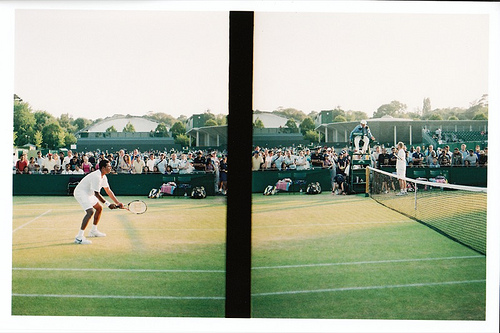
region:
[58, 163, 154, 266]
man holding a tennis racket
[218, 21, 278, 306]
a pole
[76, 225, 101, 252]
man wearing white shoes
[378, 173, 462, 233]
a tennis net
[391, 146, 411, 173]
a person wearing white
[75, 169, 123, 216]
the tennis player wearing white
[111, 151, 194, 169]
people in the audience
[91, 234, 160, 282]
man standing on the tennis court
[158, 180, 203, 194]
bags on the ground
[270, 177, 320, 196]
bags on the ground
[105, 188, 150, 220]
man holding a tennis racket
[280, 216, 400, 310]
tennis court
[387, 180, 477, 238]
tennis net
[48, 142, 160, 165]
people in the audience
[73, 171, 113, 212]
tennis player wearing white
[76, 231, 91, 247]
tennis player wearing white shoes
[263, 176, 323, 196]
bags on the side of court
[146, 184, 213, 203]
bags on the ground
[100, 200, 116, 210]
white sweat band on arm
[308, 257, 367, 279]
white line on tennis court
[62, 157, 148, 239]
A MAN IS HOLD A TENNIS RACQUET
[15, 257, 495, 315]
WHITE LINES ARE ON THE COURT FLOOR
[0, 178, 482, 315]
COURT FLOOR IS GREEN IN COLOR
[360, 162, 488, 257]
A NET SEPARATES THE SIDES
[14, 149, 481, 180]
SPECTATORS ARE WATCHING THE GAME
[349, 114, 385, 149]
REFEREE IS SITTING IN THE CHAIR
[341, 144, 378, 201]
REFEREE STAND IS GREEN IN COLOR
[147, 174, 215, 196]
BAGS ARE ON THE SIDELINE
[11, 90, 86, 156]
TREES ARE IN THE BACKGROUND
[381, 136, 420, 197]
SOMEONE IS SPEAKING WITH THE REFEREE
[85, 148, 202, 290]
a man in white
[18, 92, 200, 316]
a man in white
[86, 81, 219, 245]
a man in white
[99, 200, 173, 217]
MAN IS HOLDING THE TENNIS RACKET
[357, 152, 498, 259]
A NET SEPARATES THE SIDES OF THE COURT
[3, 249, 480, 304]
WHITE LINES ARE ON THE COURT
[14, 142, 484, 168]
SPECTATORS ARE WATCHING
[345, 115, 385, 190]
THE REFEREE IS UP IN THE CHAIR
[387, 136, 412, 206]
SOMEONE IS SPEAKING TO THE REFEREE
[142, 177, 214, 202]
BAGS ARE ON THE SIDE LINES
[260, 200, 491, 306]
COURT FLOOR IS WHITE IN COLOR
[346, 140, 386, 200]
REFEREE'S STAND IS GREEN